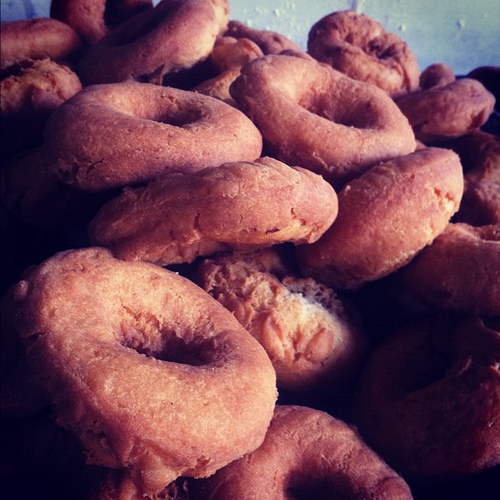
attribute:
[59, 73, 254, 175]
donut — fried to perfection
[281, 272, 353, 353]
odd topping — white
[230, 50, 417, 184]
plain donut — round, brown, fried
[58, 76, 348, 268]
plain doughnuts — brown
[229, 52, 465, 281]
brown doughnuts — crusty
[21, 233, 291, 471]
donut — biege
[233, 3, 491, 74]
wall — light, blue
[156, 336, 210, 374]
shadow — inside